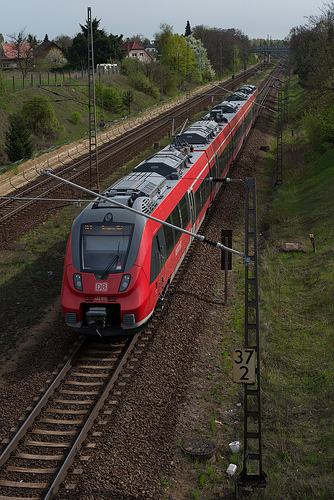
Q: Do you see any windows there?
A: Yes, there are windows.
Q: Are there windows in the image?
A: Yes, there are windows.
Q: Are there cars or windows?
A: Yes, there are windows.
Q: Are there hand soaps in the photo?
A: No, there are no hand soaps.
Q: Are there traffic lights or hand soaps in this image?
A: No, there are no hand soaps or traffic lights.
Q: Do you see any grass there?
A: Yes, there is grass.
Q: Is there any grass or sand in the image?
A: Yes, there is grass.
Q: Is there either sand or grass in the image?
A: Yes, there is grass.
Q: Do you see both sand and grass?
A: No, there is grass but no sand.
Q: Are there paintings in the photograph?
A: No, there are no paintings.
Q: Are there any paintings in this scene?
A: No, there are no paintings.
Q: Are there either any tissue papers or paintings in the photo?
A: No, there are no paintings or tissue papers.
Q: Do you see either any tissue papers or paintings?
A: No, there are no paintings or tissue papers.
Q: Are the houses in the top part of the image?
A: Yes, the houses are in the top of the image.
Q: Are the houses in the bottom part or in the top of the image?
A: The houses are in the top of the image.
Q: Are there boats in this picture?
A: No, there are no boats.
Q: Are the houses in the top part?
A: Yes, the houses are in the top of the image.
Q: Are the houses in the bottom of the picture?
A: No, the houses are in the top of the image.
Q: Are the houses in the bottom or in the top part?
A: The houses are in the top of the image.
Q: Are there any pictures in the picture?
A: No, there are no pictures.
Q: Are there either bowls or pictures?
A: No, there are no pictures or bowls.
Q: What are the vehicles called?
A: The vehicles are cars.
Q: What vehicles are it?
A: The vehicles are cars.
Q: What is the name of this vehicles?
A: These are cars.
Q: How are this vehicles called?
A: These are cars.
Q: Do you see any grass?
A: Yes, there is grass.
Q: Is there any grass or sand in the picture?
A: Yes, there is grass.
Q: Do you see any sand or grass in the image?
A: Yes, there is grass.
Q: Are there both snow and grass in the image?
A: No, there is grass but no snow.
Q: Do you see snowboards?
A: No, there are no snowboards.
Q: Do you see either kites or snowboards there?
A: No, there are no snowboards or kites.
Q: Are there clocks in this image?
A: No, there are no clocks.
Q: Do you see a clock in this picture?
A: No, there are no clocks.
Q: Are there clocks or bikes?
A: No, there are no clocks or bikes.